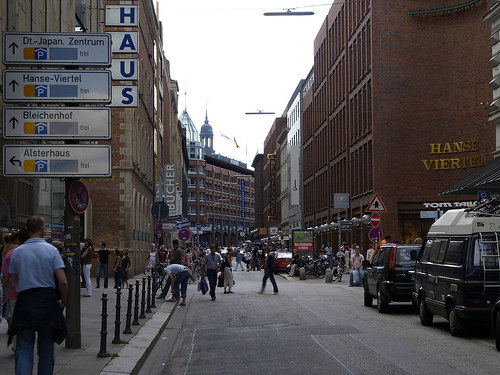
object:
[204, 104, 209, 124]
steeple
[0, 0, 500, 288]
building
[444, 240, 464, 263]
window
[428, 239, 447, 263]
window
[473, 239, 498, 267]
window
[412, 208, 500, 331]
van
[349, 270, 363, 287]
bag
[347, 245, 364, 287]
man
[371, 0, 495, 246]
wall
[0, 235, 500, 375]
street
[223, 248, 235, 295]
people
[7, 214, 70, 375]
man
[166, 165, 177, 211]
banner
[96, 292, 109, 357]
pole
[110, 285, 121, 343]
pole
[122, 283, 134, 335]
pole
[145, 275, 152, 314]
pole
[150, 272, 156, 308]
pole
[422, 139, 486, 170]
writing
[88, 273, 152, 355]
red court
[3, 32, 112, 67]
direction sign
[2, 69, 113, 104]
direction sign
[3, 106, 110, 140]
direction sign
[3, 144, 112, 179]
direction sign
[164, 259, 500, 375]
blacktop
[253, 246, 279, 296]
person crossing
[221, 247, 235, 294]
person crossing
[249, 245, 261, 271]
person crossing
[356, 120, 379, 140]
ground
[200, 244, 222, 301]
person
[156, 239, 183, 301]
person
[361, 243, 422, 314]
vehicle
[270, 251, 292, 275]
vehicle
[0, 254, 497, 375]
road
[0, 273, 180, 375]
sidewalk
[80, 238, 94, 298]
people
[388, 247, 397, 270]
taillight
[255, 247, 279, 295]
people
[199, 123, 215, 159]
dome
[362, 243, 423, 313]
jeep